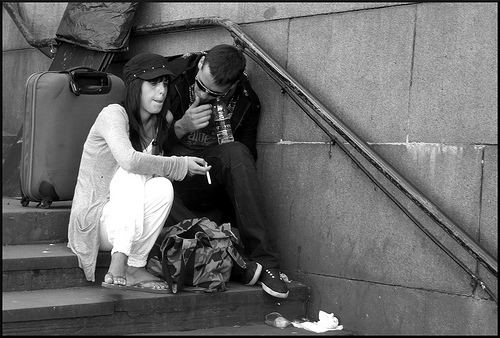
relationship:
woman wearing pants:
[67, 56, 212, 295] [99, 166, 173, 267]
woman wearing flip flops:
[67, 56, 212, 295] [101, 273, 176, 295]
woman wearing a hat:
[67, 56, 212, 295] [122, 53, 178, 83]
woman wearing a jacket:
[67, 56, 212, 295] [65, 104, 187, 281]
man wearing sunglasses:
[169, 46, 290, 299] [195, 67, 230, 99]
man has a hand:
[169, 46, 290, 299] [174, 94, 214, 141]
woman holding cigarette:
[67, 56, 212, 295] [204, 164, 211, 183]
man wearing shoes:
[169, 46, 290, 299] [235, 258, 285, 298]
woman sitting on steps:
[67, 56, 212, 295] [2, 196, 351, 336]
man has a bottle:
[169, 46, 290, 299] [215, 98, 234, 144]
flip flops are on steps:
[101, 273, 176, 295] [2, 196, 351, 336]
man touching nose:
[169, 46, 290, 299] [201, 89, 208, 103]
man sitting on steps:
[169, 46, 290, 299] [2, 196, 351, 336]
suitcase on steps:
[18, 68, 126, 208] [2, 196, 351, 336]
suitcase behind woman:
[18, 68, 126, 208] [67, 56, 212, 295]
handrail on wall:
[1, 4, 498, 280] [2, 4, 498, 336]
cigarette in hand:
[204, 164, 211, 183] [187, 155, 212, 178]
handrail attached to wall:
[1, 4, 498, 280] [2, 4, 498, 336]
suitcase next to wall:
[18, 68, 126, 208] [2, 4, 498, 336]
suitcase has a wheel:
[18, 68, 126, 208] [19, 199, 31, 206]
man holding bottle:
[169, 46, 290, 299] [215, 98, 234, 144]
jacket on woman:
[65, 104, 187, 281] [67, 56, 212, 295]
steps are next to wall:
[2, 196, 351, 336] [2, 4, 498, 336]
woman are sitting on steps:
[67, 56, 212, 295] [2, 196, 351, 336]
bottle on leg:
[215, 98, 234, 144] [195, 143, 279, 268]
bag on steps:
[152, 221, 246, 293] [2, 196, 351, 336]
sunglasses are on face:
[195, 67, 230, 99] [195, 63, 232, 105]